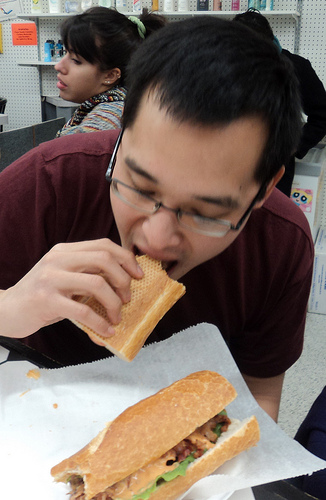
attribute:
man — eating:
[0, 17, 322, 498]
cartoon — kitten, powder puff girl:
[286, 186, 318, 216]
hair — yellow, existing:
[291, 185, 315, 201]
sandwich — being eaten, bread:
[63, 252, 194, 367]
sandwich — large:
[47, 369, 263, 499]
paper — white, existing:
[3, 318, 325, 499]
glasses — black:
[99, 116, 273, 242]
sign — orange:
[6, 19, 43, 49]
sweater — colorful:
[50, 83, 131, 139]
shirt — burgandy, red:
[0, 117, 313, 381]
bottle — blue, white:
[258, 0, 277, 13]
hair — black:
[55, 2, 167, 81]